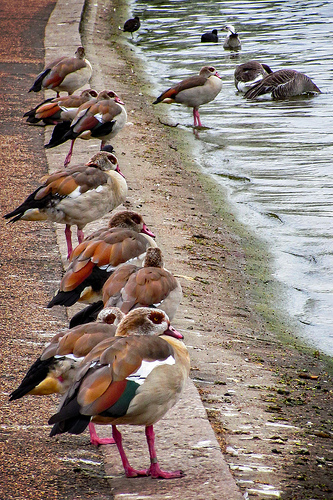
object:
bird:
[4, 46, 190, 478]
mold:
[187, 161, 312, 354]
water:
[249, 105, 329, 222]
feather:
[3, 158, 102, 225]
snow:
[243, 432, 276, 467]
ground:
[209, 375, 308, 496]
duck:
[234, 61, 322, 101]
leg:
[193, 110, 202, 128]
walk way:
[2, 9, 63, 64]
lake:
[124, 0, 333, 352]